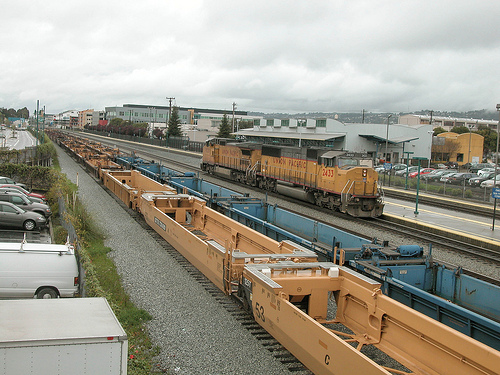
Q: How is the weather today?
A: It is cloudy.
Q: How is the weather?
A: It is cloudy.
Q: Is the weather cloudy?
A: Yes, it is cloudy.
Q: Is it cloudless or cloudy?
A: It is cloudy.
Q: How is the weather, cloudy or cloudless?
A: It is cloudy.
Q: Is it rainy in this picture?
A: No, it is cloudy.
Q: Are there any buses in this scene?
A: No, there are no buses.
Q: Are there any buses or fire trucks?
A: No, there are no buses or fire trucks.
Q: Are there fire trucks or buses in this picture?
A: No, there are no buses or fire trucks.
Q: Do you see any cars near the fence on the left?
A: Yes, there are cars near the fence.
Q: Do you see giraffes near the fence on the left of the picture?
A: No, there are cars near the fence.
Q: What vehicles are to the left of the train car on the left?
A: The vehicles are cars.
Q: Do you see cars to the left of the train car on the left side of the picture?
A: Yes, there are cars to the left of the train car.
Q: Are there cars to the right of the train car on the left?
A: No, the cars are to the left of the train car.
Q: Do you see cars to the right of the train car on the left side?
A: No, the cars are to the left of the train car.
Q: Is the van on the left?
A: Yes, the van is on the left of the image.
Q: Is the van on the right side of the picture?
A: No, the van is on the left of the image.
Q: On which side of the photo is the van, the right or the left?
A: The van is on the left of the image.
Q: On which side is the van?
A: The van is on the left of the image.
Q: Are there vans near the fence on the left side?
A: Yes, there is a van near the fence.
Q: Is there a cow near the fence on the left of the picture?
A: No, there is a van near the fence.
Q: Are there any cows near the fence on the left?
A: No, there is a van near the fence.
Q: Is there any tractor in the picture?
A: No, there are no tractors.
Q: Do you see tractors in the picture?
A: No, there are no tractors.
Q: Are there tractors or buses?
A: No, there are no tractors or buses.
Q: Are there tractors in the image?
A: No, there are no tractors.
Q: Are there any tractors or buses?
A: No, there are no tractors or buses.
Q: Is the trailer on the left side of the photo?
A: Yes, the trailer is on the left of the image.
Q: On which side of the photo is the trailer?
A: The trailer is on the left of the image.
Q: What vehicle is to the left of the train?
A: The vehicle is a trailer.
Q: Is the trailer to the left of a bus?
A: No, the trailer is to the left of the train.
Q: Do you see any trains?
A: Yes, there is a train.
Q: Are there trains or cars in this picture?
A: Yes, there is a train.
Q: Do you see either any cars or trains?
A: Yes, there is a train.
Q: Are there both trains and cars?
A: Yes, there are both a train and a car.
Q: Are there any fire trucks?
A: No, there are no fire trucks.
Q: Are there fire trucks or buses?
A: No, there are no fire trucks or buses.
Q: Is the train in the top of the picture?
A: No, the train is in the bottom of the image.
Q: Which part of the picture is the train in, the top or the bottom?
A: The train is in the bottom of the image.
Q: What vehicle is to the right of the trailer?
A: The vehicle is a train.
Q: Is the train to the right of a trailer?
A: Yes, the train is to the right of a trailer.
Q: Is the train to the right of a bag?
A: No, the train is to the right of a trailer.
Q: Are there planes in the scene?
A: No, there are no planes.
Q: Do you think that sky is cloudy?
A: Yes, the sky is cloudy.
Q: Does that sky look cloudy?
A: Yes, the sky is cloudy.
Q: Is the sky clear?
A: No, the sky is cloudy.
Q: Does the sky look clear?
A: No, the sky is cloudy.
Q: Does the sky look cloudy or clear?
A: The sky is cloudy.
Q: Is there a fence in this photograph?
A: Yes, there is a fence.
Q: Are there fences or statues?
A: Yes, there is a fence.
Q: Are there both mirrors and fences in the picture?
A: No, there is a fence but no mirrors.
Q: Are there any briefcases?
A: No, there are no briefcases.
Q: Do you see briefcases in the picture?
A: No, there are no briefcases.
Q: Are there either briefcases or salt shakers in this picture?
A: No, there are no briefcases or salt shakers.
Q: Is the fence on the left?
A: Yes, the fence is on the left of the image.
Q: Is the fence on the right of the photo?
A: No, the fence is on the left of the image.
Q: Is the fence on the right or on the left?
A: The fence is on the left of the image.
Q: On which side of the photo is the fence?
A: The fence is on the left of the image.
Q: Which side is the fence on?
A: The fence is on the left of the image.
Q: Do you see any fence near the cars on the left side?
A: Yes, there is a fence near the cars.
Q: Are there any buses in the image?
A: No, there are no buses.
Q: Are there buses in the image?
A: No, there are no buses.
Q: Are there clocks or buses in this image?
A: No, there are no buses or clocks.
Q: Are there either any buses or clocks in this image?
A: No, there are no buses or clocks.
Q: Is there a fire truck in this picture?
A: No, there are no fire trucks.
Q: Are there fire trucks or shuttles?
A: No, there are no fire trucks or shuttles.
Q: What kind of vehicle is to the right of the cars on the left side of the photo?
A: The vehicle is a train car.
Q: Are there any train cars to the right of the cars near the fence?
A: Yes, there is a train car to the right of the cars.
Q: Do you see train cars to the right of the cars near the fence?
A: Yes, there is a train car to the right of the cars.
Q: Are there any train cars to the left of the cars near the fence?
A: No, the train car is to the right of the cars.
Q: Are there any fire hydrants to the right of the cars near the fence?
A: No, there is a train car to the right of the cars.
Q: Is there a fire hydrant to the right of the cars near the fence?
A: No, there is a train car to the right of the cars.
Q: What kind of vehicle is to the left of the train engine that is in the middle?
A: The vehicle is a train car.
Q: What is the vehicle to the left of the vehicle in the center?
A: The vehicle is a train car.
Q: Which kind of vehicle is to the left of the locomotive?
A: The vehicle is a train car.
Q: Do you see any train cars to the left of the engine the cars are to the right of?
A: Yes, there is a train car to the left of the locomotive.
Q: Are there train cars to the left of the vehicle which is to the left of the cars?
A: Yes, there is a train car to the left of the locomotive.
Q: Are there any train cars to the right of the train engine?
A: No, the train car is to the left of the train engine.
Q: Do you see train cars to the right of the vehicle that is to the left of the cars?
A: No, the train car is to the left of the train engine.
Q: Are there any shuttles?
A: No, there are no shuttles.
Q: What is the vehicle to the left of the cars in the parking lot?
A: The vehicle is a locomotive.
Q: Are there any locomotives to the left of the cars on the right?
A: Yes, there is a locomotive to the left of the cars.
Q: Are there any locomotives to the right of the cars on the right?
A: No, the locomotive is to the left of the cars.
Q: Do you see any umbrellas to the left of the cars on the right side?
A: No, there is a locomotive to the left of the cars.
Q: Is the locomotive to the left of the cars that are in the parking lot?
A: Yes, the locomotive is to the left of the cars.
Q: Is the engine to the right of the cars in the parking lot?
A: No, the engine is to the left of the cars.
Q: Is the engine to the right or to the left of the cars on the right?
A: The engine is to the left of the cars.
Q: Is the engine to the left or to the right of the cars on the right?
A: The engine is to the left of the cars.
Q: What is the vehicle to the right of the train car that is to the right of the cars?
A: The vehicle is a locomotive.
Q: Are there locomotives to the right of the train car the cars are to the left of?
A: Yes, there is a locomotive to the right of the train car.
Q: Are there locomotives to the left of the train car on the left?
A: No, the locomotive is to the right of the train car.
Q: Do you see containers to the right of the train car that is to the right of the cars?
A: No, there is a locomotive to the right of the train car.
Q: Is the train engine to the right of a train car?
A: Yes, the train engine is to the right of a train car.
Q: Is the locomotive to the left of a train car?
A: No, the locomotive is to the right of a train car.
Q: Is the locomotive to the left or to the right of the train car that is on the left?
A: The locomotive is to the right of the train car.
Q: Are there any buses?
A: No, there are no buses.